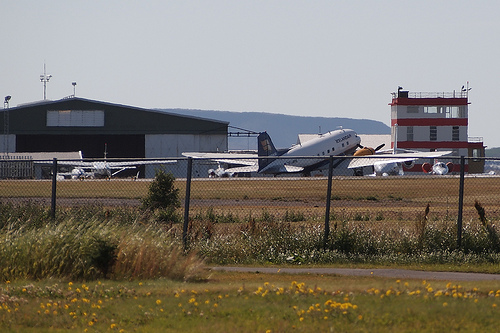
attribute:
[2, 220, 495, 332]
grass — green, vegetation, tall, flowered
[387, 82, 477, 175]
control tower — white, red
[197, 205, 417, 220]
weeds — tall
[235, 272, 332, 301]
flowers — yellow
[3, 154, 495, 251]
fence — chain link, gray, metal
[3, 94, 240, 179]
airplane hanger — green, gray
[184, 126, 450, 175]
airplane — propeller driven, large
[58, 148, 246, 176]
airplanes — small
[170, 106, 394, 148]
hill — distant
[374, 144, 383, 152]
blade — black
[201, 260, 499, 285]
road — small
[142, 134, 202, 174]
door — open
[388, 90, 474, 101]
fence — metal